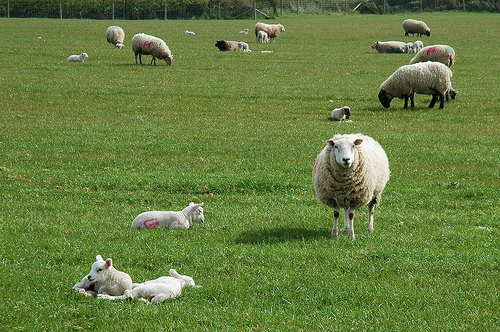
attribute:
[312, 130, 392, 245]
sheep — standing, white, adult, fully-grown, wooly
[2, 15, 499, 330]
field — grassy, grass, large, green, ground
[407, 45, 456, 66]
sheep — standing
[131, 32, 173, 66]
sheep — feeding, white, eating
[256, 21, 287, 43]
sheep — standing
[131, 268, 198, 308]
lamb — lying, baby, sheep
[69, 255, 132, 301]
lamb — lying, baby, sheep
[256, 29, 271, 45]
lamb — standing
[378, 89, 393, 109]
face — black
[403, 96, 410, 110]
leg — black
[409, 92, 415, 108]
leg — black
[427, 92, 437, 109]
leg — black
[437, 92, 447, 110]
leg — black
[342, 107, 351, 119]
face — black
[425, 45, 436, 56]
letter — red, h, marking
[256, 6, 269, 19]
brace — diagonal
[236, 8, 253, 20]
brace — diagonal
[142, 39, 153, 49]
letter — h, red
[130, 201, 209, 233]
lamb — white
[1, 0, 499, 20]
bushes — green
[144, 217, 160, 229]
marking — red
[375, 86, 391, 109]
head — black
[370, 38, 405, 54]
sheep — mother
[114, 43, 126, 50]
head — white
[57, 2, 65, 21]
post — wood